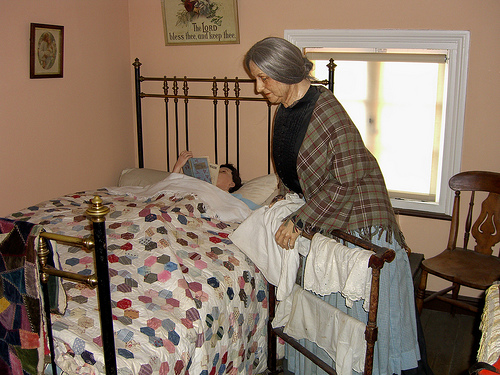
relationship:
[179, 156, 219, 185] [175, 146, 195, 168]
book in persons hand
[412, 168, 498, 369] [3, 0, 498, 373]
chair in room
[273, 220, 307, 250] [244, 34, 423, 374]
hand on old woman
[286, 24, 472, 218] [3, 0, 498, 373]
window in room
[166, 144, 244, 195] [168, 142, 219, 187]
boy reading a book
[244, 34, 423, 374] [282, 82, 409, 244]
old woman wearing shall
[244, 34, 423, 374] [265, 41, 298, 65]
old woman has hair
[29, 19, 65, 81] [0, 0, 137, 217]
picture on wall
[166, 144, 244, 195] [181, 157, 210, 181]
boy reading a book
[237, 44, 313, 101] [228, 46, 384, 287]
head of a woman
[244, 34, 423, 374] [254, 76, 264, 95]
old woman has nose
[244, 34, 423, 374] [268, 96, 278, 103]
old woman has chin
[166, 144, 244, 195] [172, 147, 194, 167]
boy has hand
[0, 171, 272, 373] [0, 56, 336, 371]
quilt on bed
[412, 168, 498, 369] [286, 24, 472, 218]
chair next to window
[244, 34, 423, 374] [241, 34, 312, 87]
old woman has gray hair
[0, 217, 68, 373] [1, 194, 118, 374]
quilt on footboard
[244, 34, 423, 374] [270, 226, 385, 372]
old woman uses quilt rack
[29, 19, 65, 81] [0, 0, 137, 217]
picture hanging on wall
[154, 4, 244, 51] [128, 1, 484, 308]
picture hanging on wall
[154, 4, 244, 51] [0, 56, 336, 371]
picture hanging on bed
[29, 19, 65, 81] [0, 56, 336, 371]
picture hanging on bed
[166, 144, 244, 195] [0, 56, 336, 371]
boy in bed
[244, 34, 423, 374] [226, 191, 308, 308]
old woman doing linen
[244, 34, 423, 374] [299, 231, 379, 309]
old woman doing linen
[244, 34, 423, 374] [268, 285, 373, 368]
old woman doing linen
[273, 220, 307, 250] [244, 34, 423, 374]
hand of old woman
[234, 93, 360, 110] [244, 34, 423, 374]
neck of old woman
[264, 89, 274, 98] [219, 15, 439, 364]
mouth of woman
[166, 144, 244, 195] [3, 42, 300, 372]
boy reading in bed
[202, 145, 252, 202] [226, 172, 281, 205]
head resting on pillow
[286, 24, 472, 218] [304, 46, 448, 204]
window with blind